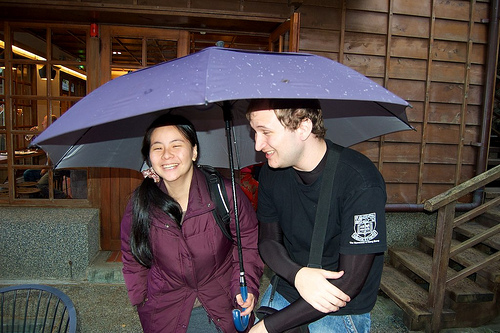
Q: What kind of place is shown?
A: It is a shop.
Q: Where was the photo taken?
A: It was taken at the shop.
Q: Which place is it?
A: It is a shop.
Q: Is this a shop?
A: Yes, it is a shop.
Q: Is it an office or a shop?
A: It is a shop.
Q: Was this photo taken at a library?
A: No, the picture was taken in a shop.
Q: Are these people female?
A: No, they are both male and female.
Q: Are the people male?
A: No, they are both male and female.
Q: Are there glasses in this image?
A: No, there are no glasses.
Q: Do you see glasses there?
A: No, there are no glasses.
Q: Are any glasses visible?
A: No, there are no glasses.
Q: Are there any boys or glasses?
A: No, there are no glasses or boys.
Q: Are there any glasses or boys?
A: No, there are no glasses or boys.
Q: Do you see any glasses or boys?
A: No, there are no glasses or boys.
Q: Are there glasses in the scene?
A: No, there are no glasses.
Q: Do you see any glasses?
A: No, there are no glasses.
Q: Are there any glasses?
A: No, there are no glasses.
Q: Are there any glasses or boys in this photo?
A: No, there are no glasses or boys.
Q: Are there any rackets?
A: No, there are no rackets.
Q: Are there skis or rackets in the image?
A: No, there are no rackets or skis.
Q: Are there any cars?
A: No, there are no cars.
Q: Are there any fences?
A: No, there are no fences.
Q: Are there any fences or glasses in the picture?
A: No, there are no fences or glasses.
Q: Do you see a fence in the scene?
A: No, there are no fences.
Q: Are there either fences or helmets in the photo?
A: No, there are no fences or helmets.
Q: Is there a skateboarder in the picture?
A: No, there are no skateboarders.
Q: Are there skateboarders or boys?
A: No, there are no skateboarders or boys.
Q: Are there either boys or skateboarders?
A: No, there are no skateboarders or boys.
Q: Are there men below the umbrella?
A: Yes, there is a man below the umbrella.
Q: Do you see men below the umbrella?
A: Yes, there is a man below the umbrella.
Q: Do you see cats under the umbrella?
A: No, there is a man under the umbrella.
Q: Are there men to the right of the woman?
A: Yes, there is a man to the right of the woman.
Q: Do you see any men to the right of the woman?
A: Yes, there is a man to the right of the woman.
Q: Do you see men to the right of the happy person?
A: Yes, there is a man to the right of the woman.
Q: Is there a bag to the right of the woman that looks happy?
A: No, there is a man to the right of the woman.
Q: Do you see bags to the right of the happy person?
A: No, there is a man to the right of the woman.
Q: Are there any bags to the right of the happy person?
A: No, there is a man to the right of the woman.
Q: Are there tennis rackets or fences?
A: No, there are no tennis rackets or fences.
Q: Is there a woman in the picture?
A: Yes, there is a woman.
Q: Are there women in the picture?
A: Yes, there is a woman.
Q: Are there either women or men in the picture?
A: Yes, there is a woman.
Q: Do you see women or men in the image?
A: Yes, there is a woman.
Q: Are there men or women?
A: Yes, there is a woman.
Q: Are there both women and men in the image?
A: Yes, there are both a woman and a man.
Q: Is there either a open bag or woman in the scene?
A: Yes, there is an open woman.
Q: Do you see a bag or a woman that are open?
A: Yes, the woman is open.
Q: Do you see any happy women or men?
A: Yes, there is a happy woman.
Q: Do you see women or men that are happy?
A: Yes, the woman is happy.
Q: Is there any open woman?
A: Yes, there is an open woman.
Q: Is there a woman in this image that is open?
A: Yes, there is a woman that is open.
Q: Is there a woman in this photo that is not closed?
A: Yes, there is a open woman.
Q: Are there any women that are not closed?
A: Yes, there is a open woman.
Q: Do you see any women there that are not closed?
A: Yes, there is a open woman.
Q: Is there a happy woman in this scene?
A: Yes, there is a happy woman.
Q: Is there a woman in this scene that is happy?
A: Yes, there is a woman that is happy.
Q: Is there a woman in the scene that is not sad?
A: Yes, there is a happy woman.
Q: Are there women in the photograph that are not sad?
A: Yes, there is a happy woman.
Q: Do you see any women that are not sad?
A: Yes, there is a happy woman.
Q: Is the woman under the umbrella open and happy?
A: Yes, the woman is open and happy.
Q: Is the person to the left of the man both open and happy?
A: Yes, the woman is open and happy.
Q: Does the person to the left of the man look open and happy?
A: Yes, the woman is open and happy.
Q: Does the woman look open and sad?
A: No, the woman is open but happy.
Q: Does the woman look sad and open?
A: No, the woman is open but happy.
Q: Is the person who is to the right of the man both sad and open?
A: No, the woman is open but happy.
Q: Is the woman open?
A: Yes, the woman is open.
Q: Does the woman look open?
A: Yes, the woman is open.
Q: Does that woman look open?
A: Yes, the woman is open.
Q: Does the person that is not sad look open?
A: Yes, the woman is open.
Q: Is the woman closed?
A: No, the woman is open.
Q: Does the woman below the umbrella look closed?
A: No, the woman is open.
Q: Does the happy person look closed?
A: No, the woman is open.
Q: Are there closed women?
A: No, there is a woman but she is open.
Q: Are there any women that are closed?
A: No, there is a woman but she is open.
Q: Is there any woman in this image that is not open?
A: No, there is a woman but she is open.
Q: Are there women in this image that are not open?
A: No, there is a woman but she is open.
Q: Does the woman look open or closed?
A: The woman is open.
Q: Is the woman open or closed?
A: The woman is open.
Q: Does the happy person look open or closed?
A: The woman is open.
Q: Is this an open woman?
A: Yes, this is an open woman.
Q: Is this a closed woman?
A: No, this is an open woman.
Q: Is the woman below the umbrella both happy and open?
A: Yes, the woman is happy and open.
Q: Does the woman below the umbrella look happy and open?
A: Yes, the woman is happy and open.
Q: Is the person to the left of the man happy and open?
A: Yes, the woman is happy and open.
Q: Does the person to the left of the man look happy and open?
A: Yes, the woman is happy and open.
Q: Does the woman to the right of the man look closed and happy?
A: No, the woman is happy but open.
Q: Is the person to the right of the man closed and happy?
A: No, the woman is happy but open.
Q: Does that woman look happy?
A: Yes, the woman is happy.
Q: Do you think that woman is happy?
A: Yes, the woman is happy.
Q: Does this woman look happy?
A: Yes, the woman is happy.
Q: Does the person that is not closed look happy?
A: Yes, the woman is happy.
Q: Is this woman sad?
A: No, the woman is happy.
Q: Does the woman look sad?
A: No, the woman is happy.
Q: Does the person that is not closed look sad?
A: No, the woman is happy.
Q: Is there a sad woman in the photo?
A: No, there is a woman but she is happy.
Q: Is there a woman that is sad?
A: No, there is a woman but she is happy.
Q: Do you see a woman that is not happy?
A: No, there is a woman but she is happy.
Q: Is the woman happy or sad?
A: The woman is happy.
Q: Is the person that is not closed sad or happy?
A: The woman is happy.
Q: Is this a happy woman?
A: Yes, this is a happy woman.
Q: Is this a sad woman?
A: No, this is a happy woman.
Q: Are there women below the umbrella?
A: Yes, there is a woman below the umbrella.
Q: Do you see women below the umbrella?
A: Yes, there is a woman below the umbrella.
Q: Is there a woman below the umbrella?
A: Yes, there is a woman below the umbrella.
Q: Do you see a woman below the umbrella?
A: Yes, there is a woman below the umbrella.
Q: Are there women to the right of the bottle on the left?
A: Yes, there is a woman to the right of the bottle.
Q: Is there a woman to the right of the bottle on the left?
A: Yes, there is a woman to the right of the bottle.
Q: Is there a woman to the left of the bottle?
A: No, the woman is to the right of the bottle.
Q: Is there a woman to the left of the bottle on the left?
A: No, the woman is to the right of the bottle.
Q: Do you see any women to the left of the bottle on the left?
A: No, the woman is to the right of the bottle.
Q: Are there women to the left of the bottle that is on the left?
A: No, the woman is to the right of the bottle.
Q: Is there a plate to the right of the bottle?
A: No, there is a woman to the right of the bottle.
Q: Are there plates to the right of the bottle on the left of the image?
A: No, there is a woman to the right of the bottle.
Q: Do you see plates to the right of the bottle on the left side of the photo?
A: No, there is a woman to the right of the bottle.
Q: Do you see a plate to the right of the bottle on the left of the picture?
A: No, there is a woman to the right of the bottle.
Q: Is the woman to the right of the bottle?
A: Yes, the woman is to the right of the bottle.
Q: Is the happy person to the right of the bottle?
A: Yes, the woman is to the right of the bottle.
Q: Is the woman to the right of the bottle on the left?
A: Yes, the woman is to the right of the bottle.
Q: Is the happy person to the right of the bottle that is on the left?
A: Yes, the woman is to the right of the bottle.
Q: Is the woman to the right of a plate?
A: No, the woman is to the right of the bottle.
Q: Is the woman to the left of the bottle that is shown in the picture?
A: No, the woman is to the right of the bottle.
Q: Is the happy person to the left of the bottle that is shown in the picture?
A: No, the woman is to the right of the bottle.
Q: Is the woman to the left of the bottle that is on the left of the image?
A: No, the woman is to the right of the bottle.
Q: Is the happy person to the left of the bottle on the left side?
A: No, the woman is to the right of the bottle.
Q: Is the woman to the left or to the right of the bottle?
A: The woman is to the right of the bottle.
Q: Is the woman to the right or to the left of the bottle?
A: The woman is to the right of the bottle.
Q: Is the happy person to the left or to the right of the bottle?
A: The woman is to the right of the bottle.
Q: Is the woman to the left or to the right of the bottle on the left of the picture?
A: The woman is to the right of the bottle.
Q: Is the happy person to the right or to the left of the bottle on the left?
A: The woman is to the right of the bottle.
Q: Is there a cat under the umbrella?
A: No, there is a woman under the umbrella.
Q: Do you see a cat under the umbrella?
A: No, there is a woman under the umbrella.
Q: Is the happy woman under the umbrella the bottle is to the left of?
A: Yes, the woman is under the umbrella.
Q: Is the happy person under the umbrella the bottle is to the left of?
A: Yes, the woman is under the umbrella.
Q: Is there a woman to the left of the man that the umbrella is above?
A: Yes, there is a woman to the left of the man.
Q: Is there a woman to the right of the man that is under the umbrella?
A: No, the woman is to the left of the man.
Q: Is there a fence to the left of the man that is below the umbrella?
A: No, there is a woman to the left of the man.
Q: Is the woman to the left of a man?
A: Yes, the woman is to the left of a man.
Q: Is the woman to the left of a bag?
A: No, the woman is to the left of a man.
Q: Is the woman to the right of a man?
A: No, the woman is to the left of a man.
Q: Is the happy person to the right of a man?
A: No, the woman is to the left of a man.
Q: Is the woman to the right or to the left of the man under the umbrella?
A: The woman is to the left of the man.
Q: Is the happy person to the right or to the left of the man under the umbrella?
A: The woman is to the left of the man.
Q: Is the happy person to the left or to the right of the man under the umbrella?
A: The woman is to the left of the man.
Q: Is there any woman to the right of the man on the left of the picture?
A: Yes, there is a woman to the right of the man.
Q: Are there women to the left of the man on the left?
A: No, the woman is to the right of the man.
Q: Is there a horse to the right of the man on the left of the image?
A: No, there is a woman to the right of the man.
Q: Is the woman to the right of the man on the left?
A: Yes, the woman is to the right of the man.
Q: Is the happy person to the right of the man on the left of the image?
A: Yes, the woman is to the right of the man.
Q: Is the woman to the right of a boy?
A: No, the woman is to the right of the man.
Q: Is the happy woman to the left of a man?
A: No, the woman is to the right of a man.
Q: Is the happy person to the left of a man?
A: No, the woman is to the right of a man.